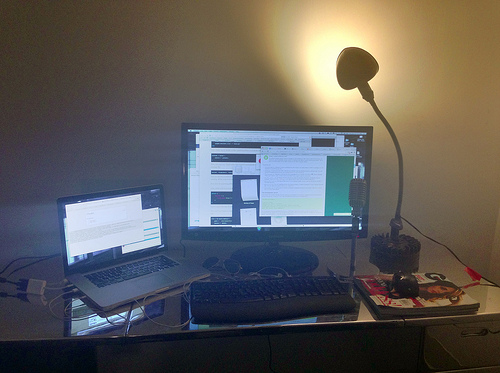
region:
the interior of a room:
[0, 0, 499, 372]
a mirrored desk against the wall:
[0, 233, 499, 372]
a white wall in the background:
[0, 0, 499, 371]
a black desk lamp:
[335, 46, 420, 256]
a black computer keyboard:
[188, 274, 356, 324]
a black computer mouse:
[392, 268, 418, 297]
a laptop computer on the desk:
[55, 183, 211, 312]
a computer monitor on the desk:
[179, 121, 373, 273]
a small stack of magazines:
[352, 270, 479, 318]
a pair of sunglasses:
[200, 254, 243, 274]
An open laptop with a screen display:
[55, 183, 210, 310]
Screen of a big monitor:
[188, 130, 370, 230]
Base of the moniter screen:
[227, 240, 318, 273]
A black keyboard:
[190, 276, 355, 327]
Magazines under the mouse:
[357, 272, 481, 317]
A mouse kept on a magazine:
[392, 273, 418, 298]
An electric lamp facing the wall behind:
[335, 46, 378, 89]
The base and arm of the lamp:
[357, 83, 420, 273]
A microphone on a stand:
[350, 178, 367, 210]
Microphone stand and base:
[326, 215, 380, 278]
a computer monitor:
[171, 122, 376, 246]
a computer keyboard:
[175, 270, 352, 330]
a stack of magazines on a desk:
[373, 284, 483, 331]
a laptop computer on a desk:
[73, 180, 175, 312]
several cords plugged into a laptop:
[40, 270, 82, 324]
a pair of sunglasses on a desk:
[203, 248, 248, 276]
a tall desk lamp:
[373, 92, 422, 255]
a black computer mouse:
[366, 264, 427, 319]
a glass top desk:
[0, 303, 242, 354]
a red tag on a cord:
[458, 260, 490, 286]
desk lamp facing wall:
[331, 40, 423, 273]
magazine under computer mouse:
[355, 268, 480, 317]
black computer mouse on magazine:
[390, 264, 420, 299]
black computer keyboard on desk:
[185, 275, 359, 321]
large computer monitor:
[179, 115, 372, 275]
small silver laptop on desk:
[53, 179, 214, 316]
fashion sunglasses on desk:
[201, 253, 241, 273]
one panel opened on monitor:
[257, 141, 359, 218]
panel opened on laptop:
[64, 195, 149, 258]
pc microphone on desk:
[342, 172, 370, 284]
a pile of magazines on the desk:
[359, 265, 481, 317]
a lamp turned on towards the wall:
[332, 46, 428, 270]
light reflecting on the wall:
[266, 3, 405, 123]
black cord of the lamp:
[402, 217, 498, 292]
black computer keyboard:
[185, 272, 353, 326]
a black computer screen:
[175, 121, 376, 241]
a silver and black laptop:
[58, 186, 206, 316]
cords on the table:
[5, 255, 205, 334]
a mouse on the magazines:
[389, 266, 421, 297]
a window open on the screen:
[255, 142, 356, 214]